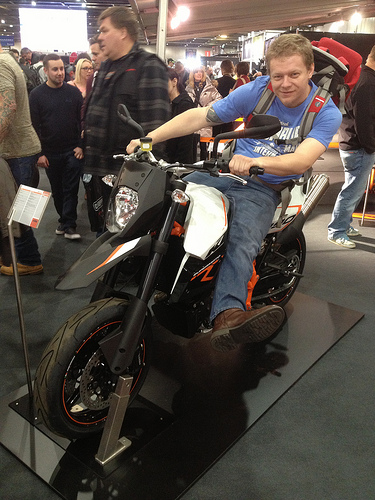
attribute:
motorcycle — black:
[71, 230, 285, 402]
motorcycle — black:
[56, 276, 256, 426]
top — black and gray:
[236, 89, 342, 164]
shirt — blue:
[240, 109, 312, 197]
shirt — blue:
[208, 94, 345, 162]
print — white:
[252, 123, 293, 182]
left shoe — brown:
[171, 292, 281, 330]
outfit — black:
[49, 95, 91, 178]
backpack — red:
[341, 37, 358, 105]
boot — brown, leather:
[205, 301, 289, 356]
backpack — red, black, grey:
[242, 34, 369, 143]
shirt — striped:
[78, 46, 169, 174]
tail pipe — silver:
[273, 171, 331, 252]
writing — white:
[264, 125, 301, 141]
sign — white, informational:
[6, 178, 54, 232]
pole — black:
[4, 221, 49, 419]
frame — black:
[114, 241, 169, 367]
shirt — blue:
[209, 74, 345, 189]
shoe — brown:
[205, 304, 287, 360]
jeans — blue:
[179, 162, 277, 321]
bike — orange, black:
[27, 99, 308, 448]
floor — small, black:
[232, 447, 288, 480]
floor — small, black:
[256, 422, 302, 462]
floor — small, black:
[260, 464, 295, 489]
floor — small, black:
[290, 460, 326, 489]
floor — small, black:
[293, 391, 349, 452]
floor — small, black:
[324, 454, 369, 491]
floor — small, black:
[310, 396, 362, 434]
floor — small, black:
[317, 356, 366, 398]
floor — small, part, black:
[179, 215, 373, 497]